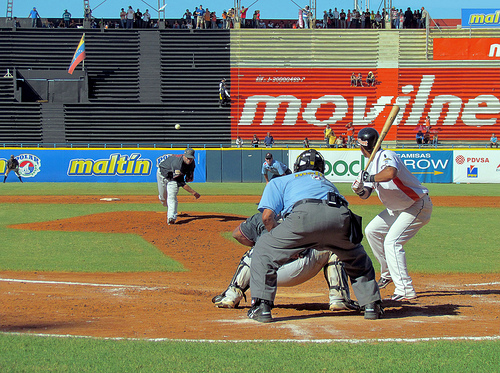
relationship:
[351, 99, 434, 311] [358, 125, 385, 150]
man wearing helmet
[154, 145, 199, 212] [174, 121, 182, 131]
pitcher throwing ball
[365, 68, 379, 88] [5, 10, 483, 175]
fan sitting in bleachers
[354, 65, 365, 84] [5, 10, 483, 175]
fan sitting in bleachers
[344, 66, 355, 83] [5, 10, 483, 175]
fan sitting in bleachers